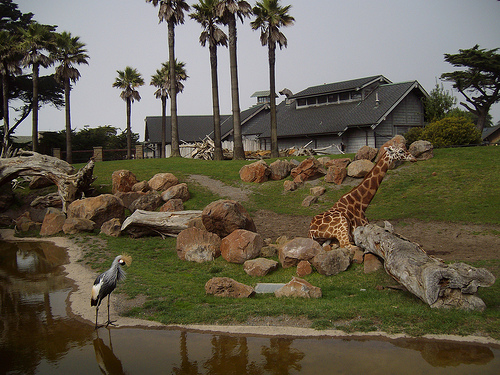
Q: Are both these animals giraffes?
A: No, they are giraffes and birds.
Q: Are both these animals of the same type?
A: No, they are giraffes and birds.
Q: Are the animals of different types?
A: Yes, they are giraffes and birds.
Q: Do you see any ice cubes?
A: No, there are no ice cubes.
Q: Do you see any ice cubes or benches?
A: No, there are no ice cubes or benches.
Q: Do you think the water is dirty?
A: Yes, the water is dirty.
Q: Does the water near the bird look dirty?
A: Yes, the water is dirty.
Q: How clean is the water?
A: The water is dirty.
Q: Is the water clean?
A: No, the water is dirty.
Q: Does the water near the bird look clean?
A: No, the water is dirty.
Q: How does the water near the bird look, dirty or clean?
A: The water is dirty.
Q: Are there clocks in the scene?
A: No, there are no clocks.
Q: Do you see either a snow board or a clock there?
A: No, there are no clocks or snowboards.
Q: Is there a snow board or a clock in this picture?
A: No, there are no clocks or snowboards.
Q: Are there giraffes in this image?
A: Yes, there is a giraffe.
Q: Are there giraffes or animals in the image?
A: Yes, there is a giraffe.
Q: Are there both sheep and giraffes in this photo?
A: No, there is a giraffe but no sheep.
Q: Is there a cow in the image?
A: No, there are no cows.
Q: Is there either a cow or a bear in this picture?
A: No, there are no cows or bears.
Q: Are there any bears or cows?
A: No, there are no cows or bears.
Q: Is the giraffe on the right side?
A: Yes, the giraffe is on the right of the image.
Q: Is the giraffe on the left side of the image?
A: No, the giraffe is on the right of the image.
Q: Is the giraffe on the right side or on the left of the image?
A: The giraffe is on the right of the image.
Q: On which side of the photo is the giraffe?
A: The giraffe is on the right of the image.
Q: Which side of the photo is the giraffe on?
A: The giraffe is on the right of the image.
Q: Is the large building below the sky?
A: Yes, the building is below the sky.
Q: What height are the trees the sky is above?
A: The trees are tall.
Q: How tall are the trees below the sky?
A: The trees are tall.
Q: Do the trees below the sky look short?
A: No, the trees are tall.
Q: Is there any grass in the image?
A: Yes, there is grass.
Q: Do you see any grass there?
A: Yes, there is grass.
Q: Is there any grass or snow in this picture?
A: Yes, there is grass.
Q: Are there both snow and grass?
A: No, there is grass but no snow.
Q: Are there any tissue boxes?
A: No, there are no tissue boxes.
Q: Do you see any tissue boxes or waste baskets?
A: No, there are no tissue boxes or waste baskets.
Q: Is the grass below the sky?
A: Yes, the grass is below the sky.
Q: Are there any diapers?
A: No, there are no diapers.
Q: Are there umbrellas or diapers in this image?
A: No, there are no diapers or umbrellas.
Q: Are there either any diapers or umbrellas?
A: No, there are no diapers or umbrellas.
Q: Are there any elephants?
A: No, there are no elephants.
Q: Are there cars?
A: No, there are no cars.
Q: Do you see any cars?
A: No, there are no cars.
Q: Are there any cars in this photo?
A: No, there are no cars.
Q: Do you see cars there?
A: No, there are no cars.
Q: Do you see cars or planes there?
A: No, there are no cars or planes.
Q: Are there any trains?
A: No, there are no trains.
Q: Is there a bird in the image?
A: Yes, there is a bird.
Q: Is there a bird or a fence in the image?
A: Yes, there is a bird.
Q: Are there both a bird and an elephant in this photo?
A: No, there is a bird but no elephants.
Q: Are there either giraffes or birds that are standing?
A: Yes, the bird is standing.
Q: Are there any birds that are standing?
A: Yes, there is a bird that is standing.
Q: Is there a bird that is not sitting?
A: Yes, there is a bird that is standing.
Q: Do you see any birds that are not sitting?
A: Yes, there is a bird that is standing .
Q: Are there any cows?
A: No, there are no cows.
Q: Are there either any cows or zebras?
A: No, there are no cows or zebras.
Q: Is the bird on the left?
A: Yes, the bird is on the left of the image.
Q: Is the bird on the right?
A: No, the bird is on the left of the image.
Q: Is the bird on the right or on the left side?
A: The bird is on the left of the image.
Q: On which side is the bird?
A: The bird is on the left of the image.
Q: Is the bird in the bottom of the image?
A: Yes, the bird is in the bottom of the image.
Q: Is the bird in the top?
A: No, the bird is in the bottom of the image.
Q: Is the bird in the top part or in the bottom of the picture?
A: The bird is in the bottom of the image.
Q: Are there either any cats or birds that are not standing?
A: No, there is a bird but it is standing.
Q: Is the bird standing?
A: Yes, the bird is standing.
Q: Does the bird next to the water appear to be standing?
A: Yes, the bird is standing.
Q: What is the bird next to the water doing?
A: The bird is standing.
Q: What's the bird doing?
A: The bird is standing.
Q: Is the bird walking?
A: No, the bird is standing.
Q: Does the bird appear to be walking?
A: No, the bird is standing.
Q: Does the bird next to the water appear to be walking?
A: No, the bird is standing.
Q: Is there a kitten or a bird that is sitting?
A: No, there is a bird but it is standing.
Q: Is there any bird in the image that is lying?
A: No, there is a bird but it is standing.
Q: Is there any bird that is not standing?
A: No, there is a bird but it is standing.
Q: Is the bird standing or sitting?
A: The bird is standing.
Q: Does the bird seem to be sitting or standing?
A: The bird is standing.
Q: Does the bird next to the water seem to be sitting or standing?
A: The bird is standing.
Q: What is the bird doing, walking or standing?
A: The bird is standing.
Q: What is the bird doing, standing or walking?
A: The bird is standing.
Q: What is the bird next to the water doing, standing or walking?
A: The bird is standing.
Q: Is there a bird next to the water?
A: Yes, there is a bird next to the water.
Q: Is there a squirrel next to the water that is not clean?
A: No, there is a bird next to the water.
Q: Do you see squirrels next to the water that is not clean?
A: No, there is a bird next to the water.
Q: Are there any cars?
A: No, there are no cars.